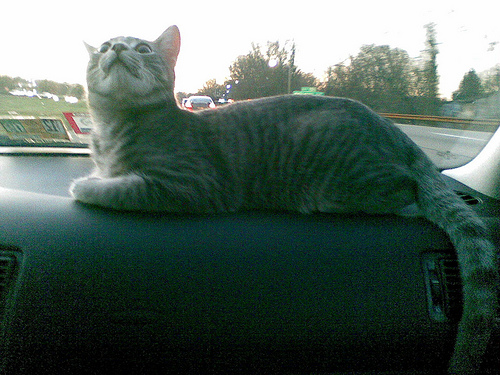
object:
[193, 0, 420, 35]
sky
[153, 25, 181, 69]
ear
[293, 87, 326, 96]
sign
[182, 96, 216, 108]
vehicle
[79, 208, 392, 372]
dashboard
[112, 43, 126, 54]
nose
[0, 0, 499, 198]
windshield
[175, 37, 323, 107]
tree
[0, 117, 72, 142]
sticker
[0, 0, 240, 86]
daytime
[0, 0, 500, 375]
photo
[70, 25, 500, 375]
cat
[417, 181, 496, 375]
tail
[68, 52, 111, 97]
white whiskers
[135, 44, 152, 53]
eye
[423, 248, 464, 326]
air vent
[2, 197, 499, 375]
car board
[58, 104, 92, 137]
decal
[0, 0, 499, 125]
background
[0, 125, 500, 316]
going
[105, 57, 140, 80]
something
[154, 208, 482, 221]
sitting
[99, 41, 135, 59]
up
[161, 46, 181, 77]
up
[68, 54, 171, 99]
up